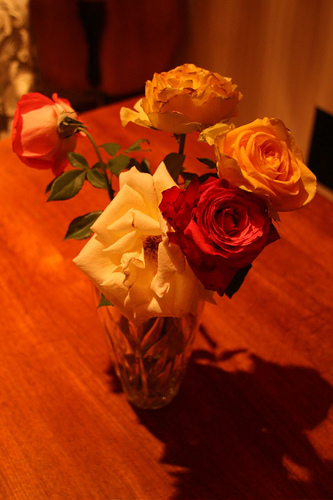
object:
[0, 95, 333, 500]
tabletop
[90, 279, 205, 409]
crystal vase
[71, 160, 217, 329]
flowers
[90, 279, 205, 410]
vase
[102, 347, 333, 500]
shadow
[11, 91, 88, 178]
flower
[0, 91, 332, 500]
table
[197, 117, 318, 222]
flowers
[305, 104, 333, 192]
chair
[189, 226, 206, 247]
petal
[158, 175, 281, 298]
flower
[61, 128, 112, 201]
stem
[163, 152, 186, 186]
stem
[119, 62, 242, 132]
flower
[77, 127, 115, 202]
rose stem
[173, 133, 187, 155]
rose stem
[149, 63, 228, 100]
wilting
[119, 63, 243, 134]
petals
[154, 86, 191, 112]
petal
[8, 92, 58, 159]
petal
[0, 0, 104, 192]
behind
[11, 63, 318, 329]
group